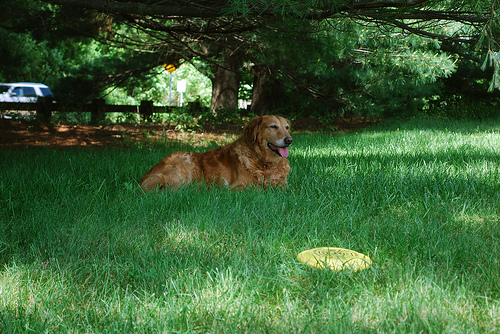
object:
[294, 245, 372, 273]
frisbee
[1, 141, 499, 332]
grass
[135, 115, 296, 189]
dog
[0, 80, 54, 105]
car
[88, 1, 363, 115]
trees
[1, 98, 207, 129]
fence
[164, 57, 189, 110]
sign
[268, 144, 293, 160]
mouth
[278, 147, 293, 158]
tongue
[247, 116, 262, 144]
ears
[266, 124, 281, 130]
eyes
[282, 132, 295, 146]
nose